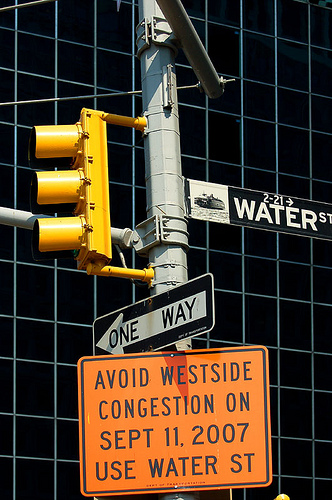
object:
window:
[243, 294, 278, 351]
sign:
[77, 345, 273, 496]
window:
[14, 412, 56, 459]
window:
[276, 36, 310, 94]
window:
[56, 270, 97, 326]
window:
[14, 360, 55, 416]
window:
[242, 113, 277, 172]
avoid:
[94, 367, 149, 389]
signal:
[30, 216, 84, 255]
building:
[0, 0, 332, 500]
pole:
[136, 0, 192, 350]